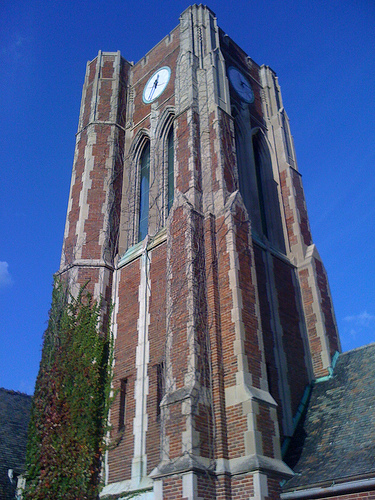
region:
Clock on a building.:
[138, 65, 181, 101]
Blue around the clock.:
[140, 68, 186, 108]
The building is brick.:
[201, 306, 232, 340]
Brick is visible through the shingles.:
[322, 375, 374, 408]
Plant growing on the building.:
[49, 324, 106, 373]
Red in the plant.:
[38, 389, 72, 445]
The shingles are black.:
[0, 402, 43, 441]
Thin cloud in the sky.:
[335, 309, 374, 348]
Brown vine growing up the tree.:
[166, 275, 207, 315]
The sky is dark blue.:
[17, 94, 71, 147]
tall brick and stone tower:
[50, 12, 347, 485]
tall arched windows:
[107, 108, 197, 270]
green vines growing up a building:
[24, 261, 124, 489]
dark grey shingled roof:
[272, 332, 372, 497]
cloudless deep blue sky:
[13, 9, 363, 400]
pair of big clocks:
[109, 11, 285, 135]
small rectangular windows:
[111, 350, 175, 457]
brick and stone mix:
[70, 37, 133, 267]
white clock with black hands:
[139, 49, 216, 115]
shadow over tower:
[205, 18, 336, 409]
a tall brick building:
[56, 21, 312, 497]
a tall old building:
[58, 21, 316, 497]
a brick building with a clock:
[56, 42, 347, 320]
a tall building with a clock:
[47, 17, 353, 186]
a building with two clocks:
[88, 26, 319, 199]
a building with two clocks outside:
[108, 39, 321, 162]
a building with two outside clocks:
[86, 10, 368, 203]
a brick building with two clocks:
[70, 36, 297, 243]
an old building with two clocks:
[62, 13, 364, 246]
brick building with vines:
[56, 21, 299, 262]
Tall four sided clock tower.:
[84, 5, 311, 498]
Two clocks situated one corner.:
[127, 48, 272, 115]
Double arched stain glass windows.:
[125, 109, 189, 250]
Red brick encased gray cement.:
[214, 190, 285, 495]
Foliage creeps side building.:
[33, 224, 121, 496]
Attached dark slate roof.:
[302, 343, 374, 495]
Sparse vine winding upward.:
[152, 194, 210, 497]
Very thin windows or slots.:
[114, 355, 168, 444]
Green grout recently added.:
[303, 339, 356, 394]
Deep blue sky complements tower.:
[209, 14, 373, 152]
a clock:
[103, 36, 205, 122]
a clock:
[103, 47, 200, 111]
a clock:
[103, 37, 229, 103]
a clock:
[105, 61, 188, 134]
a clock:
[106, 52, 219, 133]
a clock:
[122, 49, 182, 124]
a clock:
[102, 44, 226, 145]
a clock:
[111, 45, 202, 123]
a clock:
[93, 52, 194, 143]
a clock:
[95, 49, 286, 140]